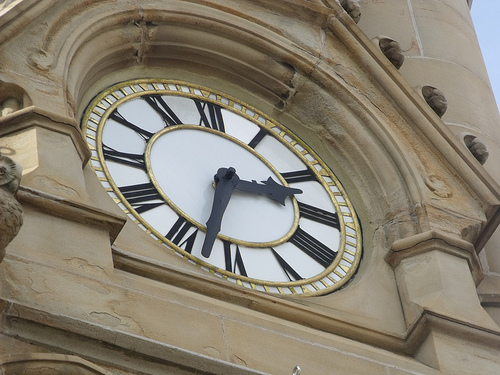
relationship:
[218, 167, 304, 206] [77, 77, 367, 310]
hand on clock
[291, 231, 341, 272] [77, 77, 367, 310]
number on clock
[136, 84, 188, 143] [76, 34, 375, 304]
number on clock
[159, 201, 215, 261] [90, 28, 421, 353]
number on clock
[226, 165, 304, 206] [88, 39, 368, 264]
arm of clock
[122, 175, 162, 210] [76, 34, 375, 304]
number on clock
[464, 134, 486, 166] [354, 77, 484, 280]
knob on building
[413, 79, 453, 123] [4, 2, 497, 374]
knob on building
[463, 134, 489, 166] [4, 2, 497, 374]
knob on building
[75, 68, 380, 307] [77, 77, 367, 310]
filagree on clock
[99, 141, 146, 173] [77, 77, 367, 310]
numeral on clock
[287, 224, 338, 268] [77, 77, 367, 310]
number are on clock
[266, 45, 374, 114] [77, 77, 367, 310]
sculptures are on top of clock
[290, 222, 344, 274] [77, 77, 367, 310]
number on clock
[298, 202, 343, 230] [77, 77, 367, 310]
number on clock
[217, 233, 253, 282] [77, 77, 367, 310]
number on clock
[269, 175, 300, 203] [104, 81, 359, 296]
arrow on clock